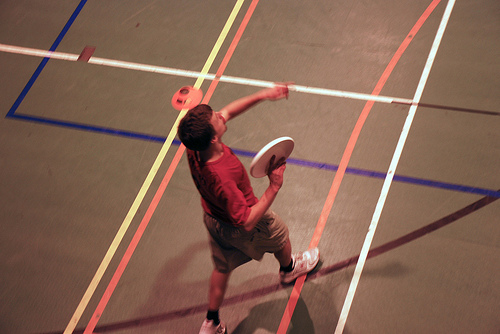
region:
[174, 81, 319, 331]
a man playing frisbee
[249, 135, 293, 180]
a white round frisbee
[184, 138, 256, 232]
a men's red t-shirt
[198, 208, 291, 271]
a light brown pair of shorts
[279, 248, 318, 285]
a white tennis shoe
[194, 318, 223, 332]
a white tennis shoe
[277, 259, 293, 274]
a man's black sock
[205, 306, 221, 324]
a man's black sock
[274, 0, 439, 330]
a long red line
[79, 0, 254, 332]
a long red line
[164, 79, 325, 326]
man walking on gray court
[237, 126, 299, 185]
hand holding white frisbee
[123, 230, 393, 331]
frisbee player's shadow on the floor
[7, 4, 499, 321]
gray court with colored lines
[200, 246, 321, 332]
black socks and white shoes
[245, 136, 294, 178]
white frisbee held sideways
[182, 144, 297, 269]
red shirt and khaki pants of man with frisbee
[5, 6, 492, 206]
blue lines on the court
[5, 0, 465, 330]
white lines on the court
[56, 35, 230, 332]
light yellow line on the court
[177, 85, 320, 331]
man in red shirt and shorts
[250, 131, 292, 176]
a white Frisbee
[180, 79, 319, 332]
man holding a white frisbee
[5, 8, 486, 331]
a court with multi-colored lines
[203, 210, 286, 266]
khaki shorts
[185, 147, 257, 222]
a short-sleeve red t-shirt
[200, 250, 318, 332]
white tennis shoes with black socks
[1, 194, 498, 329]
dark purple line under the man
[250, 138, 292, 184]
Frisbee in the man's right hand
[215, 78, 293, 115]
man's left arm pointing forward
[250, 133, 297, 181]
a Frisbee in his hand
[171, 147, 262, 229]
a red tshirt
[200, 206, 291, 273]
knee length khaki shorts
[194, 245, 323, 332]
a pair of white athletic sneakers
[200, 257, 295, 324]
ankle length black socks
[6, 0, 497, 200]
a blue line on the ground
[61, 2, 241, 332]
a yellow line on the ground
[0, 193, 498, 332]
a curved burgundy line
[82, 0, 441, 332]
two orange lines on the ground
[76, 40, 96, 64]
a small burgundy rectangle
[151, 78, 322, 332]
man holding white frisbee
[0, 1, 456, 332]
white lines painted on the floor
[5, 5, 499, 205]
blue lines painted on the floor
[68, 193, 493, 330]
black line painted on the floor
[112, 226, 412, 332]
shadow of frisbee player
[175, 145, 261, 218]
red shirt of man holding frisbee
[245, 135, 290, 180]
white frisbee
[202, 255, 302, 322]
black socks of man holding frisbee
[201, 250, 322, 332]
white shoes of man holding frisbee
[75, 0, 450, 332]
orange lines painted on the floor